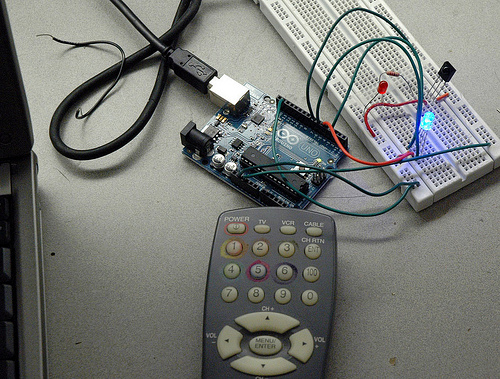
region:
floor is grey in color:
[59, 213, 179, 357]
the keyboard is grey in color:
[216, 212, 328, 376]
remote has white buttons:
[236, 217, 310, 355]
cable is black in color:
[111, 34, 171, 102]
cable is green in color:
[312, 57, 369, 111]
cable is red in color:
[362, 92, 397, 166]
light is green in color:
[421, 110, 446, 125]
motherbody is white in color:
[283, 9, 328, 52]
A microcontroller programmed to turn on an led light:
[156, 59, 467, 219]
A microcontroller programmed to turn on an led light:
[174, 57, 489, 215]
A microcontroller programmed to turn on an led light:
[178, 56, 489, 216]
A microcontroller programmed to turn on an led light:
[176, 56, 493, 220]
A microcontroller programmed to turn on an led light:
[176, 58, 489, 221]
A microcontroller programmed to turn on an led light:
[177, 55, 494, 215]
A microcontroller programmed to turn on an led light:
[178, 58, 485, 218]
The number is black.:
[225, 238, 242, 255]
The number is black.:
[250, 240, 268, 259]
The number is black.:
[275, 235, 297, 260]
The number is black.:
[222, 258, 243, 278]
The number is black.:
[249, 262, 266, 278]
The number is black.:
[272, 259, 292, 279]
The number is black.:
[220, 282, 238, 302]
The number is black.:
[245, 285, 263, 302]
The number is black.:
[271, 285, 291, 305]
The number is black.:
[302, 287, 317, 305]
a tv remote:
[188, 204, 356, 374]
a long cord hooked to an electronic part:
[46, 2, 223, 164]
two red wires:
[322, 93, 455, 165]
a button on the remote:
[300, 221, 324, 241]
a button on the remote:
[287, 224, 306, 235]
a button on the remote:
[250, 222, 270, 234]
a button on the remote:
[302, 238, 324, 265]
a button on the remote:
[272, 236, 288, 253]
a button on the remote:
[251, 246, 271, 260]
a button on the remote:
[222, 234, 239, 254]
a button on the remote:
[289, 261, 314, 283]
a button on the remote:
[244, 264, 276, 284]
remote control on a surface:
[197, 202, 339, 376]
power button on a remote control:
[223, 222, 248, 234]